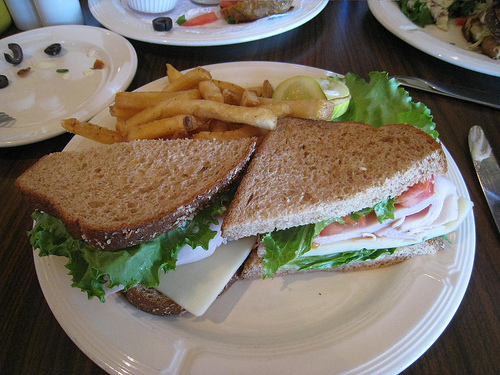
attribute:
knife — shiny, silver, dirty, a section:
[468, 123, 499, 232]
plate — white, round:
[31, 61, 478, 374]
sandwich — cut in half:
[13, 117, 474, 317]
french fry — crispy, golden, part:
[60, 118, 127, 142]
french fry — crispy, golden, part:
[127, 115, 198, 141]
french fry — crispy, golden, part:
[162, 101, 278, 132]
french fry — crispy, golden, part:
[163, 68, 212, 91]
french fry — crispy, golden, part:
[260, 97, 336, 122]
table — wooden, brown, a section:
[1, 1, 499, 373]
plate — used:
[0, 24, 137, 149]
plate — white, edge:
[87, 1, 327, 46]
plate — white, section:
[367, 2, 498, 77]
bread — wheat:
[14, 136, 256, 253]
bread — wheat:
[122, 265, 243, 316]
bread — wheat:
[221, 115, 445, 243]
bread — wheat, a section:
[238, 226, 456, 280]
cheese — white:
[154, 233, 257, 316]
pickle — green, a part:
[273, 76, 351, 122]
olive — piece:
[152, 16, 174, 32]